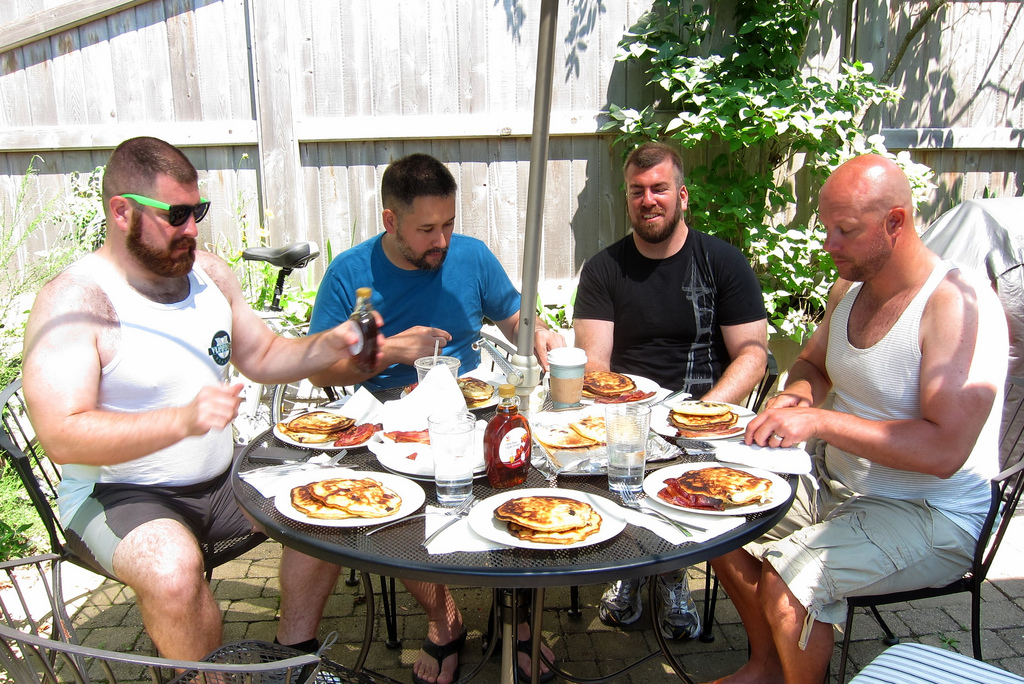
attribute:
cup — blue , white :
[547, 346, 586, 407]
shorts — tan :
[742, 437, 978, 650]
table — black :
[228, 374, 798, 678]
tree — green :
[598, 0, 934, 343]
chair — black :
[2, 379, 269, 668]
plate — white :
[639, 458, 792, 513]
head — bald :
[818, 155, 911, 279]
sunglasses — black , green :
[117, 191, 210, 224]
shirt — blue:
[312, 232, 521, 384]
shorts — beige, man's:
[740, 440, 1000, 647]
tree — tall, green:
[597, 3, 905, 348]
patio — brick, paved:
[0, 452, 1021, 680]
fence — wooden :
[3, 3, 1019, 305]